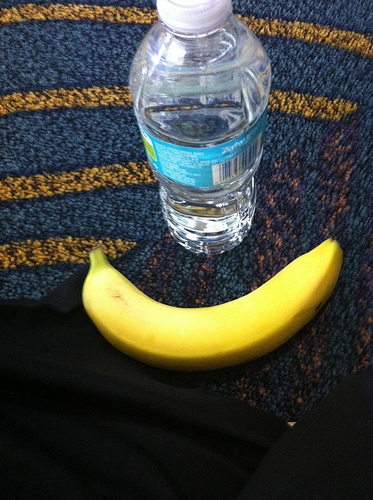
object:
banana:
[80, 236, 345, 373]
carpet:
[0, 0, 372, 425]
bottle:
[127, 0, 272, 257]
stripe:
[0, 160, 157, 202]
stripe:
[0, 86, 134, 116]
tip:
[89, 246, 108, 267]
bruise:
[114, 291, 128, 306]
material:
[80, 236, 372, 499]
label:
[137, 105, 268, 192]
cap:
[154, 0, 233, 35]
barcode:
[211, 131, 263, 186]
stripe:
[0, 236, 137, 269]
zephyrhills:
[217, 127, 259, 154]